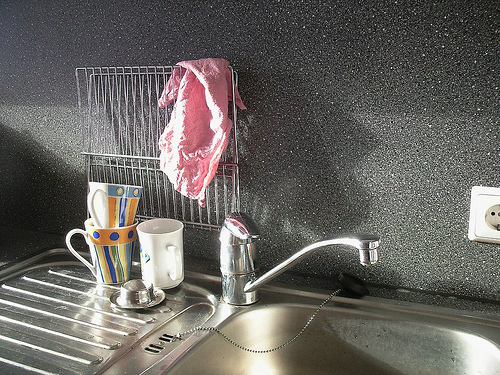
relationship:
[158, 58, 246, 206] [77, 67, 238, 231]
cloth on top of rack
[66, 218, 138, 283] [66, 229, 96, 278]
cup has handle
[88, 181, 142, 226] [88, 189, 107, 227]
cup has handle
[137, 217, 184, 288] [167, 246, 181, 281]
cup has handle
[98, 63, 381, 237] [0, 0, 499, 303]
shadow on top of wall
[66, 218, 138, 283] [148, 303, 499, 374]
cup next to sink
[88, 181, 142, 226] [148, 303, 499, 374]
cup next to sink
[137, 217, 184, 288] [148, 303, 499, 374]
cup next to sink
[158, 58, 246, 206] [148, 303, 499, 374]
cloth next to sink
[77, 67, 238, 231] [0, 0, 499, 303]
rack against wall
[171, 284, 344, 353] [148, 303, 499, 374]
chain connected to sink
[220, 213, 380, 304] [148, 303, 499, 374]
faucet next to sink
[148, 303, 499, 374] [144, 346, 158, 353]
sink has drain hole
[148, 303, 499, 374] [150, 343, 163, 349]
sink has drain hole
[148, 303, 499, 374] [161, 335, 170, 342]
sink has drain hole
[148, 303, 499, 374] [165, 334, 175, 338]
sink has drain hole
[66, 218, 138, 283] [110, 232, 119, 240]
cup has blue dot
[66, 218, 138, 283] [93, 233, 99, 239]
cup has blue dot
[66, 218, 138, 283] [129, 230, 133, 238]
cup has blue dot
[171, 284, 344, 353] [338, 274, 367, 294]
chain connected to stopper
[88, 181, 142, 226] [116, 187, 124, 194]
cup has yellow dot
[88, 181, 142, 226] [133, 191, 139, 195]
cup has yellow dot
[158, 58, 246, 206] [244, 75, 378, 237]
cloth has shadow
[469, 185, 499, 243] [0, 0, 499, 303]
outlet connected to wall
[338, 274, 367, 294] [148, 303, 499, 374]
stopper connected to sink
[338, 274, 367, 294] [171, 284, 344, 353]
stopper has chain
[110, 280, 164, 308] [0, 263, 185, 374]
lid on top of sink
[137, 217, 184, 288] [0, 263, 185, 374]
cup on top of sink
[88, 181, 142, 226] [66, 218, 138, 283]
cup on top of cup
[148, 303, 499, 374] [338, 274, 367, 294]
sink has stopper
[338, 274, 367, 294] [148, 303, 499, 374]
stopper behind sink